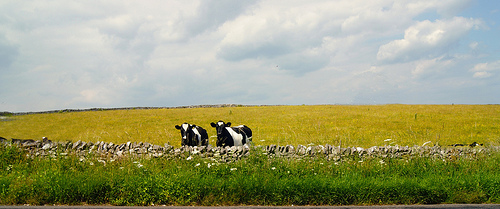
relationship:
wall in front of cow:
[0, 137, 500, 170] [210, 116, 254, 148]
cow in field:
[210, 116, 254, 148] [0, 104, 500, 144]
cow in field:
[173, 120, 209, 150] [0, 104, 500, 144]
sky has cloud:
[0, 1, 500, 104] [374, 16, 476, 67]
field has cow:
[0, 104, 500, 144] [210, 116, 254, 148]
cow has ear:
[210, 116, 254, 148] [226, 121, 232, 128]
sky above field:
[0, 1, 500, 104] [0, 104, 500, 144]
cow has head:
[210, 116, 254, 148] [210, 118, 233, 140]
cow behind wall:
[210, 116, 254, 148] [0, 137, 500, 170]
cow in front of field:
[210, 116, 254, 148] [0, 104, 500, 144]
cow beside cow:
[210, 116, 254, 148] [173, 120, 209, 150]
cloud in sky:
[374, 16, 476, 67] [0, 1, 500, 104]